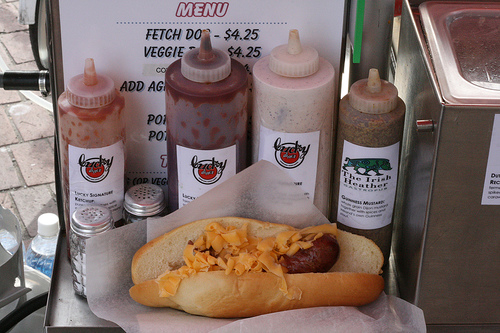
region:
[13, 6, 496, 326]
picture taken outdoors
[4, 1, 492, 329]
picture taken during the day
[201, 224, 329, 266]
a hot dog covered with cheese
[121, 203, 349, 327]
the hot dog has a bun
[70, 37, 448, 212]
various sauces next to the hot dog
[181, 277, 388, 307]
the bun of the hot dog is white and yellow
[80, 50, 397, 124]
the bottles are open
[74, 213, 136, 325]
a salt shaker behind the hotdog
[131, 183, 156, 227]
a pepper shaker behind the hotdog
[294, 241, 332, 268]
the hot dog is slight burnt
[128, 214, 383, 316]
A hotdog with cheese on it.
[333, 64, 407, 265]
A bottle of mustard.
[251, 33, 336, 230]
A large condiment bottle.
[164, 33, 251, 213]
A condiment bottle with red sauce.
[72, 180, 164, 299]
A set of salt and pepper shakers.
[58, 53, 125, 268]
A bottle with ketchup in it.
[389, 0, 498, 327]
A metal food storage bin.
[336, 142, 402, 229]
A white and green label.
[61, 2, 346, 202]
A white menu sign.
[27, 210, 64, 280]
A water bottle.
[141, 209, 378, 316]
a hot dog on a bun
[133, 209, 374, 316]
a hot dog sitting in a bun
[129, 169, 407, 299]
cheese on a hot dog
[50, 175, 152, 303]
a salt shaker near a hot dog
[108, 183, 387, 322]
a hot dog near a salt shaker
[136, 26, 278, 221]
bbq sauce near a hot dog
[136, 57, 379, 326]
a hot dog near some bbq sauce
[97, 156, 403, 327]
a hot dog sitting on a wrapper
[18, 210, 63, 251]
a top on a water bottle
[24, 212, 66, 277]
a water bottle in the background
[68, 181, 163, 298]
a salt and pepper shaker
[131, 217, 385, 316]
a hot dog on a white paper wrapper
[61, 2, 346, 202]
a white menu against a window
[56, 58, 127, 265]
a bottle of ketchup on a metal tray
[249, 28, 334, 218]
a bottle of white sauce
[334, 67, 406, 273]
a bottle of green mustard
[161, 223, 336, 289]
orange shredded cheese on a hot dog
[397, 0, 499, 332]
a metal box next to some condiments bottles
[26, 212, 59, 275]
a bottle of water outside the window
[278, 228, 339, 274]
tip of a sausage in a hot dog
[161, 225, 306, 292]
a pile of cheddar cheese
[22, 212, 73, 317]
a plastic water bottle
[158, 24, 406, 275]
a few squeeze bottles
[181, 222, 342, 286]
a cheese covered sausage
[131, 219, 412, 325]
a sausage in a burger bun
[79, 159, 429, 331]
a white tissue paper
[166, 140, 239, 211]
a white label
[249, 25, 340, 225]
a bottle of ranch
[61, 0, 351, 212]
a white menu sign